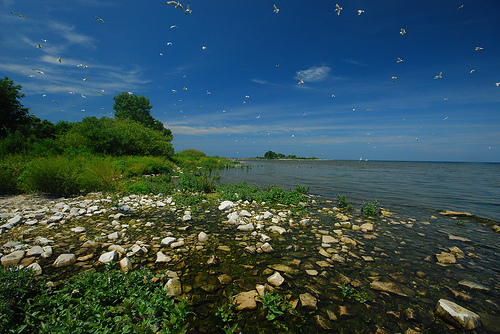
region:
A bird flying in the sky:
[394, 54, 403, 65]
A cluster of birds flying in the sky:
[2, 3, 498, 143]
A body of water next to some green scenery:
[216, 148, 498, 226]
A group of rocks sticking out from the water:
[0, 184, 495, 332]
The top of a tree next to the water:
[111, 91, 163, 131]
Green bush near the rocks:
[0, 158, 165, 193]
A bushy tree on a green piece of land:
[0, 80, 28, 161]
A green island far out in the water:
[227, 152, 325, 162]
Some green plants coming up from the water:
[212, 178, 315, 205]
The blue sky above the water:
[0, 63, 498, 160]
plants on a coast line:
[18, 160, 109, 199]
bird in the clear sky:
[397, 27, 407, 37]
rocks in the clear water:
[261, 262, 298, 285]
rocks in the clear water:
[120, 240, 150, 252]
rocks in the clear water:
[436, 241, 467, 264]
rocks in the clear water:
[335, 217, 370, 237]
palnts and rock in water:
[260, 184, 310, 212]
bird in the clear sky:
[200, 43, 208, 53]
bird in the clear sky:
[36, 44, 44, 49]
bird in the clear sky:
[476, 44, 483, 51]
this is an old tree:
[107, 92, 175, 162]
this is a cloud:
[277, 73, 318, 92]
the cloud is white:
[289, 66, 310, 74]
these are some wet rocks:
[172, 158, 322, 313]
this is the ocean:
[261, 128, 309, 208]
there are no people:
[178, 142, 313, 214]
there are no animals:
[193, 221, 228, 255]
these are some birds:
[277, 11, 487, 110]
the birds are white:
[203, 110, 361, 252]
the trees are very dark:
[132, 79, 194, 168]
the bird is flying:
[427, 59, 449, 94]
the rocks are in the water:
[222, 242, 333, 280]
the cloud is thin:
[315, 122, 349, 148]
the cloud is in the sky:
[286, 43, 333, 100]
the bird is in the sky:
[157, 30, 176, 54]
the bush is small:
[17, 152, 99, 204]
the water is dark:
[316, 155, 441, 204]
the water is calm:
[397, 160, 479, 198]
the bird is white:
[195, 32, 209, 57]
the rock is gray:
[437, 292, 494, 332]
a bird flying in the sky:
[395, 22, 410, 38]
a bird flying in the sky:
[470, 40, 485, 55]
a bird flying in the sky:
[466, 65, 478, 77]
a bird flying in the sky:
[194, 38, 209, 55]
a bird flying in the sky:
[167, 22, 179, 32]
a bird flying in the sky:
[52, 52, 64, 66]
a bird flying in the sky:
[331, 0, 343, 22]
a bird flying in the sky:
[31, 65, 51, 76]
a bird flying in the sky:
[179, 83, 190, 96]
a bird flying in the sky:
[32, 40, 43, 50]